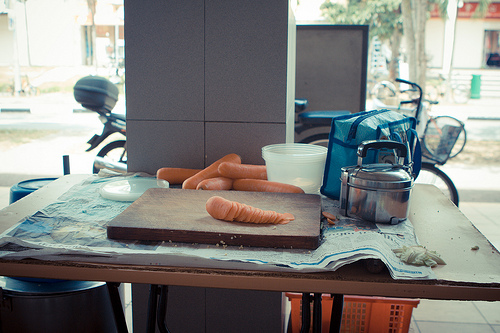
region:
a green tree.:
[318, 0, 420, 24]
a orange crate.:
[281, 292, 422, 331]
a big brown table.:
[0, 227, 497, 320]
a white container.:
[258, 130, 331, 201]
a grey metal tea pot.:
[328, 130, 430, 232]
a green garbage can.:
[460, 62, 493, 107]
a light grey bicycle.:
[389, 62, 478, 186]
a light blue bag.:
[316, 93, 426, 215]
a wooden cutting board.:
[95, 182, 337, 259]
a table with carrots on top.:
[133, 147, 318, 231]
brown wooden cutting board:
[105, 177, 326, 253]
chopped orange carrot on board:
[200, 193, 301, 228]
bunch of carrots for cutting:
[152, 152, 307, 195]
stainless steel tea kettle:
[336, 135, 416, 228]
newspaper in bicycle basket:
[433, 120, 459, 168]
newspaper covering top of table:
[1, 176, 483, 277]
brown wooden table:
[12, 170, 492, 291]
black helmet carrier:
[66, 70, 121, 116]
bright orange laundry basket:
[283, 290, 428, 330]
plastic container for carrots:
[260, 138, 330, 198]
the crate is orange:
[286, 294, 424, 326]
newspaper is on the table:
[335, 213, 421, 280]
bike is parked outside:
[83, 68, 138, 166]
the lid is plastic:
[103, 165, 175, 215]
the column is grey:
[123, 7, 293, 149]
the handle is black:
[351, 133, 421, 169]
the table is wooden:
[426, 213, 498, 329]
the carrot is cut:
[201, 190, 290, 233]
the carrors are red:
[187, 154, 284, 202]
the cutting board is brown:
[124, 181, 342, 264]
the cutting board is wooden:
[108, 180, 320, 252]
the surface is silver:
[343, 165, 420, 227]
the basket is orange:
[286, 294, 421, 331]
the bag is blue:
[329, 77, 431, 168]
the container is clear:
[256, 143, 332, 187]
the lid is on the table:
[93, 173, 173, 203]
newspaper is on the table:
[334, 220, 412, 287]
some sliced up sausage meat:
[195, 190, 300, 225]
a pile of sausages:
[162, 148, 272, 185]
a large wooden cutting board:
[105, 191, 321, 238]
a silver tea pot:
[335, 137, 417, 228]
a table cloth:
[17, 198, 111, 245]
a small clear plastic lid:
[101, 170, 168, 201]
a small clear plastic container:
[254, 133, 336, 191]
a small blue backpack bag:
[315, 108, 431, 210]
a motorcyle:
[73, 66, 150, 183]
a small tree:
[389, 0, 441, 100]